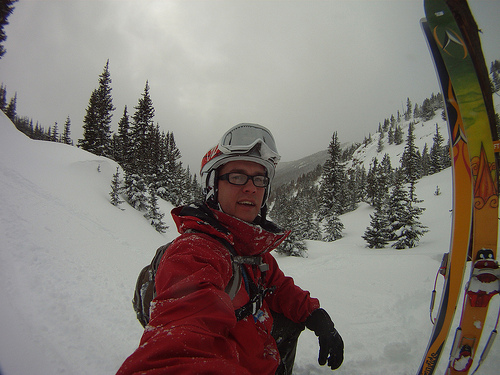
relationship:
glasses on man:
[218, 172, 271, 187] [132, 147, 302, 341]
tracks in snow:
[351, 292, 393, 324] [39, 193, 139, 346]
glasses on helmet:
[218, 172, 271, 187] [196, 135, 233, 177]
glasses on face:
[221, 173, 300, 196] [204, 164, 277, 208]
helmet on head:
[196, 135, 233, 177] [205, 116, 286, 249]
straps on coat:
[224, 261, 274, 312] [128, 202, 321, 358]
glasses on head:
[218, 172, 271, 187] [205, 116, 286, 249]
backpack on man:
[126, 255, 181, 344] [132, 147, 302, 341]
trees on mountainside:
[294, 190, 454, 253] [333, 115, 459, 284]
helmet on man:
[196, 135, 233, 177] [132, 147, 302, 341]